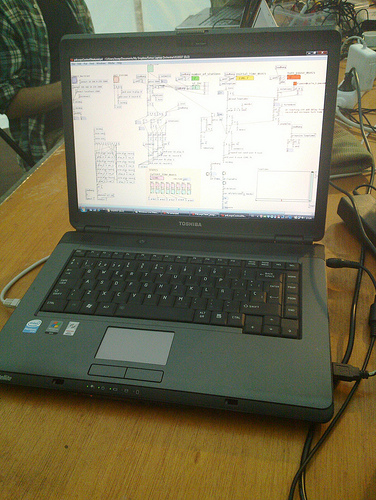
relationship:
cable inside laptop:
[322, 254, 375, 274] [6, 41, 335, 354]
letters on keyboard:
[83, 262, 231, 300] [55, 245, 305, 330]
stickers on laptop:
[25, 312, 83, 337] [6, 41, 335, 354]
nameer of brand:
[172, 216, 213, 232] [179, 220, 202, 227]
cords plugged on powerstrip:
[322, 254, 375, 274] [339, 29, 374, 120]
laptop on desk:
[6, 41, 335, 354] [8, 166, 375, 456]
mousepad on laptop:
[93, 327, 182, 365] [6, 41, 335, 354]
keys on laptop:
[83, 262, 231, 300] [6, 41, 335, 354]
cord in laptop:
[335, 256, 375, 279] [6, 41, 335, 354]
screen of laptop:
[58, 44, 328, 233] [6, 41, 335, 354]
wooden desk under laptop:
[25, 157, 57, 236] [6, 41, 335, 354]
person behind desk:
[7, 5, 102, 134] [8, 166, 375, 456]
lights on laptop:
[82, 381, 140, 406] [6, 41, 335, 354]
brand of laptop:
[171, 214, 211, 231] [6, 41, 335, 354]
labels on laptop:
[25, 312, 83, 337] [6, 41, 335, 354]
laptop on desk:
[6, 41, 335, 354] [0, 0, 376, 498]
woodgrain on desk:
[22, 173, 60, 226] [0, 0, 376, 498]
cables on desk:
[291, 3, 365, 28] [0, 0, 376, 498]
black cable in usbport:
[335, 358, 375, 384] [328, 350, 335, 399]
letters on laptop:
[83, 262, 231, 300] [6, 41, 335, 354]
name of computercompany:
[172, 216, 213, 232] [154, 219, 233, 239]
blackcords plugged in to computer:
[324, 257, 367, 378] [6, 41, 335, 354]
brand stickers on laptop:
[27, 321, 75, 336] [6, 41, 335, 354]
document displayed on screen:
[71, 62, 312, 219] [58, 44, 328, 233]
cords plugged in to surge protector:
[345, 42, 368, 124] [339, 29, 374, 120]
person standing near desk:
[7, 5, 102, 134] [0, 0, 376, 498]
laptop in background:
[183, 4, 249, 26] [14, 4, 360, 27]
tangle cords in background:
[318, 5, 370, 35] [14, 4, 360, 27]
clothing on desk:
[338, 132, 370, 175] [0, 0, 376, 498]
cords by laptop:
[345, 42, 368, 124] [6, 41, 335, 354]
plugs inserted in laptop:
[335, 358, 375, 384] [6, 41, 335, 354]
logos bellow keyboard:
[22, 318, 82, 342] [55, 245, 305, 330]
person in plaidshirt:
[7, 5, 102, 134] [1, 5, 84, 92]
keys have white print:
[145, 274, 194, 289] [83, 262, 231, 300]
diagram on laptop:
[71, 62, 312, 219] [39, 35, 333, 425]